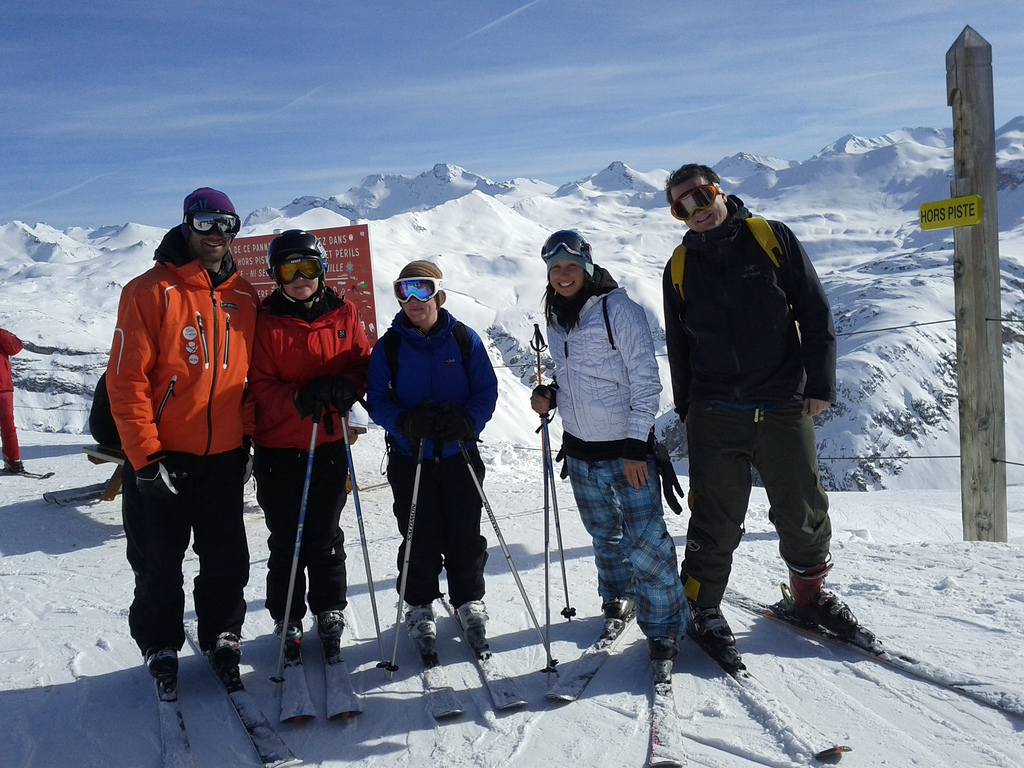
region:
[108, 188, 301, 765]
a man on skis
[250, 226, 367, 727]
a woman on skis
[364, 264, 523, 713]
a kid on skis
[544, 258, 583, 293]
face of a woman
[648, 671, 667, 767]
snow on the ski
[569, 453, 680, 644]
the pants are plaid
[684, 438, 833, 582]
the pants are black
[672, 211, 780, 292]
the straps are yellow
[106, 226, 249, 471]
the jacket is orange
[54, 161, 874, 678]
A group of skiers at the top of a hill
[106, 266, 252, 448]
An orange jacket on a skier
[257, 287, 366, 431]
A red jacket on a skier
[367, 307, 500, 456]
A blue jacket on a skier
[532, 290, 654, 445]
A white jacket on a skier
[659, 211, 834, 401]
A black jacket on a skier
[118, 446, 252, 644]
Black pants on a skier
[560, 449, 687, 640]
Blue plaid pants on a skier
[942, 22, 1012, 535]
A tall wooden fence post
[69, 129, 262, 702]
man in orange coat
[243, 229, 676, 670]
three people holding ski sticks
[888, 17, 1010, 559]
pole with yellow sign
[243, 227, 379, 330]
red sign with white writing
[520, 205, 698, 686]
woman with white jacket and plaid pants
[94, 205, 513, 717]
three people with goggles on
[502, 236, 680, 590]
woman in white jacket with goggle on her head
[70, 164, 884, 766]
A group of five skiers.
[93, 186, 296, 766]
Skier in an orange jacket.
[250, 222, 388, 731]
Skier in a red jacket.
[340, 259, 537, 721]
Skier in a blue jacket.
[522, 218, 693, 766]
Skier in a white jacket.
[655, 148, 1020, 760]
Skier in a black jacket.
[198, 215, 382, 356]
A red sign with white letters.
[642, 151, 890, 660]
Man with a backpack that has yellow straps.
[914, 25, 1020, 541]
A wooden post.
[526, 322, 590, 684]
Two ski poles being held in one hand.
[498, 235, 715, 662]
woman in a white jacket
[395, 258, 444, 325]
person has a head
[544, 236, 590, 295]
person has a head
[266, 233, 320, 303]
person has a head